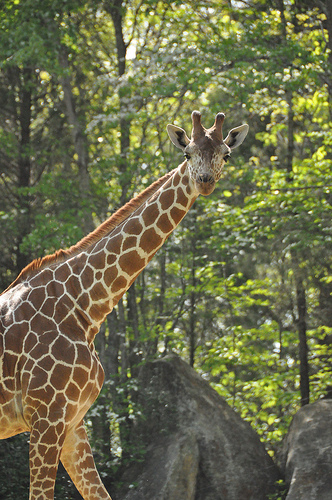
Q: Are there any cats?
A: No, there are no cats.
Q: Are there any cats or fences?
A: No, there are no cats or fences.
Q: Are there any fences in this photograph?
A: No, there are no fences.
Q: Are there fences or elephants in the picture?
A: No, there are no fences or elephants.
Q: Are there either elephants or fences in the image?
A: No, there are no fences or elephants.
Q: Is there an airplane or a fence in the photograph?
A: No, there are no fences or airplanes.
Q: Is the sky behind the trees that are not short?
A: Yes, the sky is behind the trees.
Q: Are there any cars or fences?
A: No, there are no fences or cars.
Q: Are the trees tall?
A: Yes, the trees are tall.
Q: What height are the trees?
A: The trees are tall.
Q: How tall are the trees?
A: The trees are tall.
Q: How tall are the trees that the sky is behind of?
A: The trees are tall.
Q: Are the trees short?
A: No, the trees are tall.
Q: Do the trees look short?
A: No, the trees are tall.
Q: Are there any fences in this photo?
A: No, there are no fences.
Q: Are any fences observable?
A: No, there are no fences.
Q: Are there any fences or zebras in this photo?
A: No, there are no fences or zebras.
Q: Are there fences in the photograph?
A: No, there are no fences.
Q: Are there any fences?
A: No, there are no fences.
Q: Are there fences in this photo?
A: No, there are no fences.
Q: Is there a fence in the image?
A: No, there are no fences.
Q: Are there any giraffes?
A: Yes, there is a giraffe.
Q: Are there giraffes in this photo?
A: Yes, there is a giraffe.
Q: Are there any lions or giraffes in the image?
A: Yes, there is a giraffe.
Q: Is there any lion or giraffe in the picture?
A: Yes, there is a giraffe.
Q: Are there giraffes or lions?
A: Yes, there is a giraffe.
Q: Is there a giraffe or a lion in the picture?
A: Yes, there is a giraffe.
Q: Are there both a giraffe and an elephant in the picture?
A: No, there is a giraffe but no elephants.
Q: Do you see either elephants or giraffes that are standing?
A: Yes, the giraffe is standing.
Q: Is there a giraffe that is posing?
A: Yes, there is a giraffe that is posing.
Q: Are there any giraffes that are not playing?
A: Yes, there is a giraffe that is posing.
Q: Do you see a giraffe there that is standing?
A: Yes, there is a giraffe that is standing.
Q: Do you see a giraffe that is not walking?
A: Yes, there is a giraffe that is standing .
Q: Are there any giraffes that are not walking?
A: Yes, there is a giraffe that is standing.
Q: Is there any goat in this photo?
A: No, there are no goats.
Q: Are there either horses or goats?
A: No, there are no goats or horses.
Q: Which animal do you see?
A: The animal is a giraffe.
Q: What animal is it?
A: The animal is a giraffe.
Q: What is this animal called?
A: This is a giraffe.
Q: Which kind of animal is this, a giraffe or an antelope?
A: This is a giraffe.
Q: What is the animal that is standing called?
A: The animal is a giraffe.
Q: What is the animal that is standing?
A: The animal is a giraffe.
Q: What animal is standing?
A: The animal is a giraffe.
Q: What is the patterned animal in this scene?
A: The animal is a giraffe.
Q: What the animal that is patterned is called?
A: The animal is a giraffe.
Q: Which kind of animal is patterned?
A: The animal is a giraffe.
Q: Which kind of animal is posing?
A: The animal is a giraffe.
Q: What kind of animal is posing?
A: The animal is a giraffe.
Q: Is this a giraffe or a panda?
A: This is a giraffe.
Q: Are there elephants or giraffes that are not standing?
A: No, there is a giraffe but it is standing.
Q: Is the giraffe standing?
A: Yes, the giraffe is standing.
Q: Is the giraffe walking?
A: No, the giraffe is standing.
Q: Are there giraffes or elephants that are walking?
A: No, there is a giraffe but it is standing.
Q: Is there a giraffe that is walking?
A: No, there is a giraffe but it is standing.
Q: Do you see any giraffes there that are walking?
A: No, there is a giraffe but it is standing.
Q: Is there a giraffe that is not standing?
A: No, there is a giraffe but it is standing.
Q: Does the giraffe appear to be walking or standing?
A: The giraffe is standing.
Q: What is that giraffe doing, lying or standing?
A: The giraffe is standing.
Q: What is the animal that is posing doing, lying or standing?
A: The giraffe is standing.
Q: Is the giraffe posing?
A: Yes, the giraffe is posing.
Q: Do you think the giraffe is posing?
A: Yes, the giraffe is posing.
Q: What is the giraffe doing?
A: The giraffe is posing.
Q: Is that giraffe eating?
A: No, the giraffe is posing.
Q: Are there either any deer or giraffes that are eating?
A: No, there is a giraffe but it is posing.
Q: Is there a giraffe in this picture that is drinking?
A: No, there is a giraffe but it is posing.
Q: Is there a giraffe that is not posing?
A: No, there is a giraffe but it is posing.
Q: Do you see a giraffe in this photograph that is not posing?
A: No, there is a giraffe but it is posing.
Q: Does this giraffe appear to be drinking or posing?
A: The giraffe is posing.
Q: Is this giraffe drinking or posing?
A: The giraffe is posing.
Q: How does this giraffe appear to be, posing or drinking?
A: The giraffe is posing.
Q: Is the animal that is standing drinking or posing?
A: The giraffe is posing.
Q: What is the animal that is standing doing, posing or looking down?
A: The giraffe is posing.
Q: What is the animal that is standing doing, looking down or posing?
A: The giraffe is posing.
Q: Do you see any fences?
A: No, there are no fences.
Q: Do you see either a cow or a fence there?
A: No, there are no fences or cows.